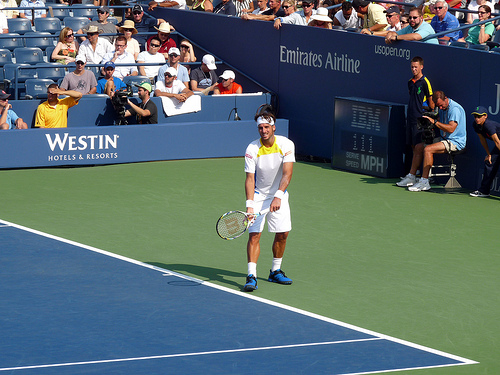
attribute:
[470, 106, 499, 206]
boy — ball boy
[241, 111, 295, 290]
player — male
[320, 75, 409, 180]
tracker — MPH tracker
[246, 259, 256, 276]
sock — white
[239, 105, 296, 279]
man — white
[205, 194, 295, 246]
racket — Wilson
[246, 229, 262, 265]
calves — muscular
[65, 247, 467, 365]
lines — white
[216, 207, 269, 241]
racket — Wilson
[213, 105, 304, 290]
tennis player — male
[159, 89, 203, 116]
towel — white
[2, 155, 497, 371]
tennis court — blue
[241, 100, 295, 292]
man — tennis player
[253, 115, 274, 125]
headband — white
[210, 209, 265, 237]
tennis racquet — Wilson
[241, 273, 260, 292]
shoe — bright blue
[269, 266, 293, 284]
shoe — bright blue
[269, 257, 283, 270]
sock — white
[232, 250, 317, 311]
shoes — blue, black, tennis shoes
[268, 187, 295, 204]
wristband — white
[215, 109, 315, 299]
player — man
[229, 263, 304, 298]
shoe — blue, black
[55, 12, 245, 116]
spectators — seated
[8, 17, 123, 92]
seats — empty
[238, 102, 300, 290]
tennis player — male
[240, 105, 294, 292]
tennis player — male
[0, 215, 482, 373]
baseline — white